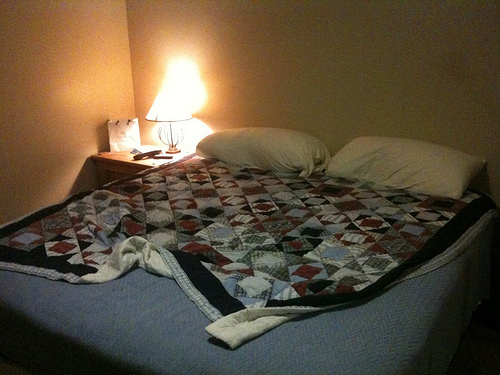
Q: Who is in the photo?
A: No people.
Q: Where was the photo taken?
A: In a room.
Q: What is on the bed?
A: Pillows.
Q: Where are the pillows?
A: On the bed.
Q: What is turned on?
A: Lights.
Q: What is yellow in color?
A: The wall.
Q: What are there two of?
A: Pillows.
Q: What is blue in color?
A: Blanket.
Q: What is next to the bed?
A: Lamp.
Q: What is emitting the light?
A: Lamp.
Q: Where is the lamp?
A: On the nightstand.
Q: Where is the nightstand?
A: In the corner of the room.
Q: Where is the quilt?
A: On the bed.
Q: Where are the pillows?
A: On the bed.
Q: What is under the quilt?
A: Blanket.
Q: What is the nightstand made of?
A: Wood.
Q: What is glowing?
A: The lamp.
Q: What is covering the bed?
A: A quilt.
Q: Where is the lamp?
A: On the night stand.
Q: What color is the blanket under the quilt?
A: Blue.